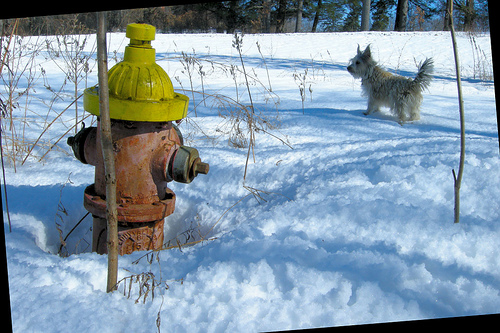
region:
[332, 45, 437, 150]
A dog standing in the snow.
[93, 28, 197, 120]
The fire hydrant is yellow on the top.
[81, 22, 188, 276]
A fire hydrant in the snow.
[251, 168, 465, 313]
The snow is white and fluffy.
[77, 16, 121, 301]
A tree branch in the snow.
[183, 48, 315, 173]
Branches in the snow.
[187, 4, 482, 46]
Trees in the background.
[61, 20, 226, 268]
A fire hydrant surrounded by snow.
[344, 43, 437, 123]
A white dog standing in the snow.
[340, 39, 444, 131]
A dog.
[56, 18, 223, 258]
The hydrant is orange and yellow.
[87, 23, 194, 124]
The top of the hydrant is yellow.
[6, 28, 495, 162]
Small plants in the snow.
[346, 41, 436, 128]
The dog is looking to the left.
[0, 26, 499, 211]
A field behind the fire hydrant.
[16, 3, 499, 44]
A line of trees beyond the field.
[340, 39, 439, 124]
small dog with ratty white fur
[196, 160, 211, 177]
small rusted bolt on a fire hydrant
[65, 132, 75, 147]
small rusted bolt on a fire hydrant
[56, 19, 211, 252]
fire hydrant with top painted yellow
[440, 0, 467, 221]
small twig with no leaves on it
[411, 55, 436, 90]
ratty looking tail on the back of a dog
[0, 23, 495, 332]
snow covered field with dog and hydrant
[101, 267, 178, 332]
dead plant in the snow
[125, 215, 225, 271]
dead plant in the snow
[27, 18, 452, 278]
this is deep snow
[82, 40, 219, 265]
this is a fire hydrant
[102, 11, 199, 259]
the hydrant is yellow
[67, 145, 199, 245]
the hydrant is orange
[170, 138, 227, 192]
the bolt is gray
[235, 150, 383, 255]
the snow is white and blue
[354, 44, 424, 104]
the dog is small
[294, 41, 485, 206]
the dog is standing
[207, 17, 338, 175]
the plants are covered in snow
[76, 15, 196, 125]
a yellow cap of the fire hydrant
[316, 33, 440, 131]
a dog outside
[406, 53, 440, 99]
tail of the dog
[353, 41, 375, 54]
ears of the dog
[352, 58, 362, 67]
an eye of the dog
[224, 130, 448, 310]
snow on the ground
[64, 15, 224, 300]
fire hydrant on snowy ground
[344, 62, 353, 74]
nose of the dog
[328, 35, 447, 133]
dog walking in ground covered with snow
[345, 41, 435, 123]
small scruffy tan dog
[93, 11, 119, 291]
long skinny leafless tree limb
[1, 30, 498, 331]
deeply packed, bright white snow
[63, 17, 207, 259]
red and yellow colored fire hydrant in snow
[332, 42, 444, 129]
little white colored puppy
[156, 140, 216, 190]
knob thing on fire hydrant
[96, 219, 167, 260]
symbol with text on fire hydrant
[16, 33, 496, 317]
baren snow covered field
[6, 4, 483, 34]
brown colored shrubbage and trees in the background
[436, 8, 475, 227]
wooden twig sticking out of ground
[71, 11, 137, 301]
barren small tree trunk growing out of the snow.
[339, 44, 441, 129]
dog standing in the snow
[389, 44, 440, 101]
dog's tail is standing straight up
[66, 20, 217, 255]
fire hydrant surrounded by snow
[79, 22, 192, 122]
top of fire hydrant is yellow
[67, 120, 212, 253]
bottom of fire hydrant is red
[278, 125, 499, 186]
shadows in the snow